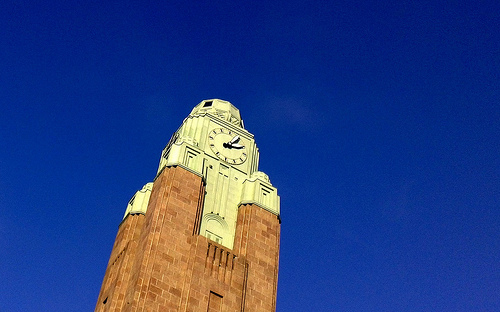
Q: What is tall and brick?
A: A tower.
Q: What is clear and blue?
A: The sky.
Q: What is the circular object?
A: A clock.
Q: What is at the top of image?
A: Tower.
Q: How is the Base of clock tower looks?
A: Bricks.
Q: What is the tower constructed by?
A: Bricks.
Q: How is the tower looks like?
A: Good.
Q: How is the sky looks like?
A: Clear.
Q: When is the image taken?
A: Sky is clear.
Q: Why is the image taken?
A: Remembrance.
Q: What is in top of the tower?
A: Clock.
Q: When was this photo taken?
A: Afternoon.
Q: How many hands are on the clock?
A: Two.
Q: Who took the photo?
A: The person standing under it.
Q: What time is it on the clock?
A: 2:05.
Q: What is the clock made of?
A: Brick.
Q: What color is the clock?
A: Yellow.